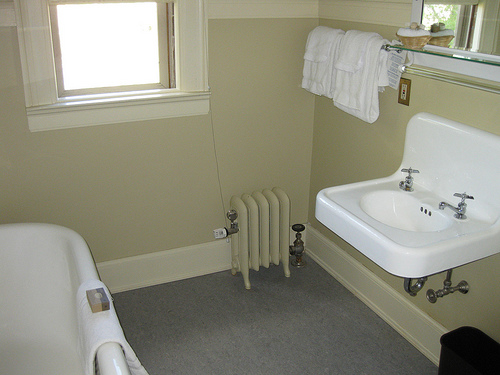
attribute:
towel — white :
[297, 23, 392, 124]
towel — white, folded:
[298, 24, 346, 101]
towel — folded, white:
[331, 29, 388, 126]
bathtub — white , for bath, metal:
[0, 218, 129, 373]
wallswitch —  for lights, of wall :
[396, 67, 410, 116]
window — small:
[31, 0, 178, 97]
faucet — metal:
[427, 186, 475, 228]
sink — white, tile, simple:
[311, 110, 499, 277]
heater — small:
[207, 179, 303, 294]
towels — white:
[298, 22, 394, 119]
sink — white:
[333, 98, 495, 295]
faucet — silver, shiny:
[429, 180, 481, 219]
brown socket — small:
[394, 76, 414, 108]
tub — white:
[0, 220, 132, 374]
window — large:
[51, 7, 207, 123]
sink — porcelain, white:
[303, 133, 488, 276]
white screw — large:
[213, 227, 228, 242]